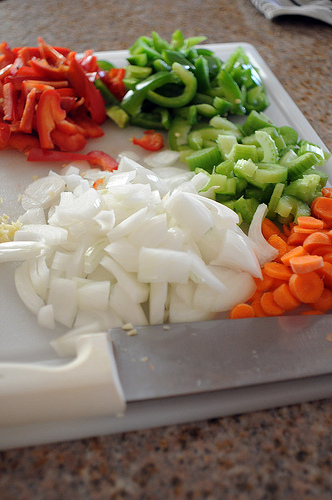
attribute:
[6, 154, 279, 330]
onions — white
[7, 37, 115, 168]
peppers — sliced, red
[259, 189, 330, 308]
carrot — round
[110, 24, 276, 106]
peppers — red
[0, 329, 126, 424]
handle — white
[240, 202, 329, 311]
carrots — sliced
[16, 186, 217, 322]
onions — chopped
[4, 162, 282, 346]
onions — chopped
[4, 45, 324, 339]
board — white, cutting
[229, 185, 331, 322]
carrots — chopped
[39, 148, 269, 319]
onions — chopped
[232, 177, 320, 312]
carrots — sliced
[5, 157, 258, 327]
onions — green, white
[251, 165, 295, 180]
celery — sliced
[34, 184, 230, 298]
white onions — chopped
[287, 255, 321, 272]
carrot — chopped, orange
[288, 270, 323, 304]
carrot — chopped, orange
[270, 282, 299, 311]
carrot — chopped, orange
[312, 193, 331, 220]
carrot — chopped, orange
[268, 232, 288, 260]
carrot — chopped, orange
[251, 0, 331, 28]
book — corner ,  background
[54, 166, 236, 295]
onions — chopped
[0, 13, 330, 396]
platter — raw chopped vegetables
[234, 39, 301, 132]
cutting board — white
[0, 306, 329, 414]
knife — chefs , Tools  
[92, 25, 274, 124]
peppers — green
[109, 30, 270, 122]
peppers — sliced, green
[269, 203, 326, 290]
carrots —  Sliced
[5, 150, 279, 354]
onion — chopped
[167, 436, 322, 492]
counter top — granite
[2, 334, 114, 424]
handle — white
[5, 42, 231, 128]
peppers — chopped, green